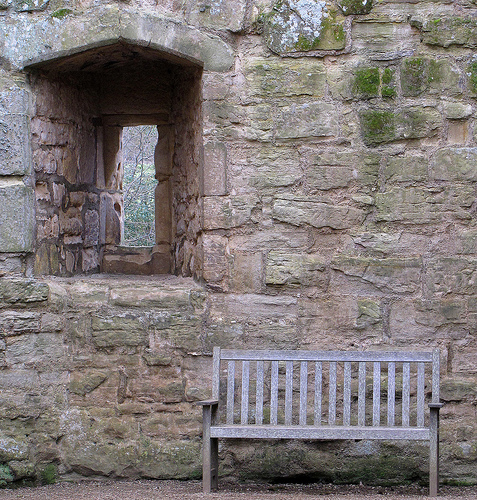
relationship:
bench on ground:
[127, 321, 475, 497] [8, 483, 475, 497]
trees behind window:
[122, 126, 158, 245] [100, 112, 172, 273]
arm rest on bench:
[198, 395, 217, 409] [193, 344, 443, 495]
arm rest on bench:
[426, 397, 444, 416] [193, 344, 443, 495]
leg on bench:
[426, 405, 442, 497] [198, 341, 441, 482]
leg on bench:
[200, 407, 216, 491] [198, 341, 441, 482]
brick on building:
[202, 141, 225, 194] [1, 0, 475, 497]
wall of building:
[0, 0, 476, 485] [1, 0, 475, 497]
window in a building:
[97, 107, 178, 259] [1, 0, 475, 497]